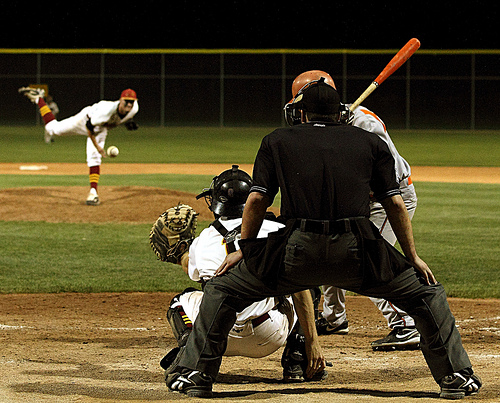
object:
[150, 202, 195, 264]
glove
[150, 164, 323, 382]
player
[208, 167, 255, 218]
helmet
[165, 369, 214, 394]
umpire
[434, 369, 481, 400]
shoes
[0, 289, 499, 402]
dirt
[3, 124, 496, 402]
field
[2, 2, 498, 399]
baseball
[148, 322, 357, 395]
down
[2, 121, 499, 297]
grass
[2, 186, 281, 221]
dirt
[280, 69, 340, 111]
helmet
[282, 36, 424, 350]
batter's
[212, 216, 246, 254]
strap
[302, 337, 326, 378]
hand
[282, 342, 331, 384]
shoe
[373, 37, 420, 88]
red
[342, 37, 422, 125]
bat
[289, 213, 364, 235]
belt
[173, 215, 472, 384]
pants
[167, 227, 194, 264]
hand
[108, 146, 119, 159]
baseball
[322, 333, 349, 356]
homeplate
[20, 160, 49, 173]
second base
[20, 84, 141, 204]
pitcher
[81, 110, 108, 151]
windup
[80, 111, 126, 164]
pitch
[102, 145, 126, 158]
motion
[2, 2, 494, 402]
game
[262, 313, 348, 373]
home plate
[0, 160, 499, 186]
dirt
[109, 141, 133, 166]
midair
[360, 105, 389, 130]
number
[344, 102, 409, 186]
back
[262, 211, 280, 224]
chest plate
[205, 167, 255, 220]
head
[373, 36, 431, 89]
top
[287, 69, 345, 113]
head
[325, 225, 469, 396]
legs